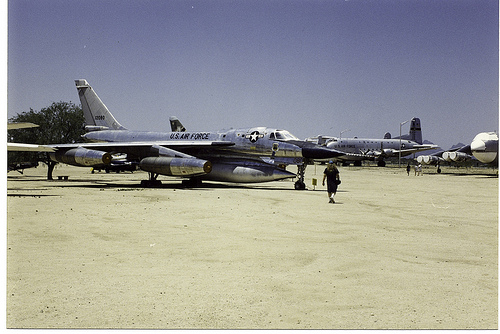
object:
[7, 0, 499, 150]
sky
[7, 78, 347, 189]
plane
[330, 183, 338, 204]
legs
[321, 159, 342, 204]
person